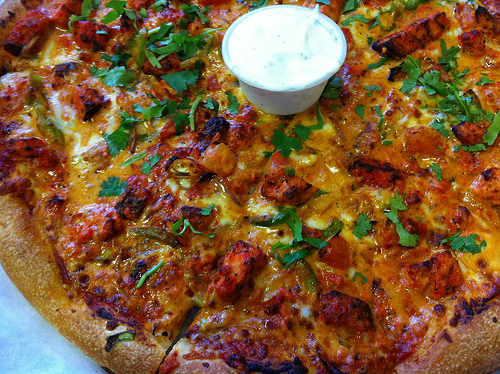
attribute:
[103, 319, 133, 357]
vegetable — burnt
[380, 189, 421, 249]
garnish — green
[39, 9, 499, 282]
cheese — orange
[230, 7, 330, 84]
dip — ranch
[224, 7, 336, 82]
dip — white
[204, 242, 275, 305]
sauce — red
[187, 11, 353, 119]
plastic container — small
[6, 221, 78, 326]
brown crust — golden-brown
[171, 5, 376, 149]
pizza and dip — round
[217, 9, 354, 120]
plastic bowl — small